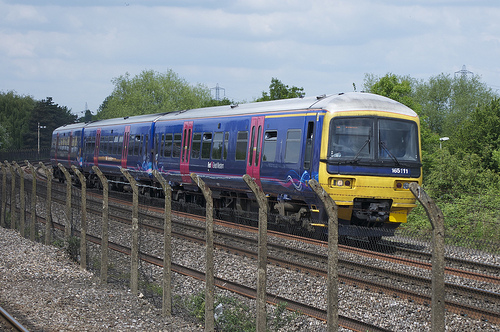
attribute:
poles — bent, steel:
[4, 162, 447, 327]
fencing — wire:
[450, 245, 499, 332]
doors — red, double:
[246, 118, 260, 176]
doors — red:
[179, 125, 192, 185]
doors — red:
[121, 125, 129, 164]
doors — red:
[91, 131, 101, 162]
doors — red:
[67, 131, 74, 166]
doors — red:
[54, 136, 59, 163]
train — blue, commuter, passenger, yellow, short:
[52, 124, 413, 239]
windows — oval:
[250, 122, 262, 165]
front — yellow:
[322, 104, 417, 225]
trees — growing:
[417, 97, 498, 219]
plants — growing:
[217, 297, 254, 332]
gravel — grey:
[5, 249, 119, 328]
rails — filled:
[1, 307, 21, 329]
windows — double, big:
[332, 120, 418, 165]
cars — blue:
[52, 128, 327, 178]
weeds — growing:
[172, 289, 203, 326]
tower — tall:
[452, 64, 473, 83]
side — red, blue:
[55, 112, 321, 180]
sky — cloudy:
[2, 9, 490, 88]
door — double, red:
[181, 120, 189, 171]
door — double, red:
[118, 127, 132, 171]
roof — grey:
[48, 92, 418, 132]